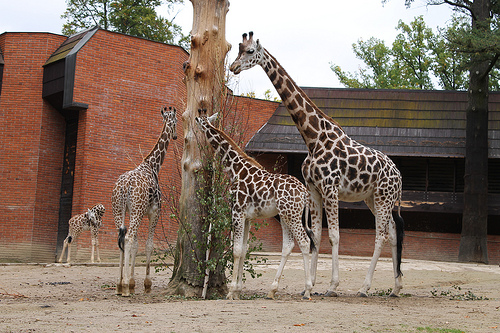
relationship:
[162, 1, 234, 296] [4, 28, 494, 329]
tree trunk in enclosure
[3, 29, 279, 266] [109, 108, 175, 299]
building behind giraffe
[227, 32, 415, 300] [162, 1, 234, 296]
giraffe standing beside tree trunk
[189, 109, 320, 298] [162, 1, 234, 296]
giraffes beside tree trunk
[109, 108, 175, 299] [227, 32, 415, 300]
giraffe facing giraffe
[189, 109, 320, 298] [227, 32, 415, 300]
giraffes standing with giraffe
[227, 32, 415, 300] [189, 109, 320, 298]
giraffe standing with giraffes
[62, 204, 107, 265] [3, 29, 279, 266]
giraffe by building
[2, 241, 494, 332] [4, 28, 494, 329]
ground in enclosure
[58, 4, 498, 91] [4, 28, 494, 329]
trees outside enclosure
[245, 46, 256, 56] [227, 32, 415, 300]
left eye of giraffe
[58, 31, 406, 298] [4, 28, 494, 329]
giraffes in enclosure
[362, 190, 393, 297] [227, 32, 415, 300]
left rear leg of giraffe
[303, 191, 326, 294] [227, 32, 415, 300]
right front leg of giraffe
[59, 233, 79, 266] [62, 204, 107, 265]
rear legs of giraffe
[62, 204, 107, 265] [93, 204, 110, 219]
giraffe with bent neck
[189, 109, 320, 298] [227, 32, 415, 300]
giraffes next to giraffe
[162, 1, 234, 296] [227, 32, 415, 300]
tree trunk beside giraffe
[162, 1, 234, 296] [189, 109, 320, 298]
tree trunk beside giraffes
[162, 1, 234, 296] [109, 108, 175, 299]
tree trunk beside giraffe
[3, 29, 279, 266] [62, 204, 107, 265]
building behind giraffe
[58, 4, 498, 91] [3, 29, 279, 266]
trees behind building